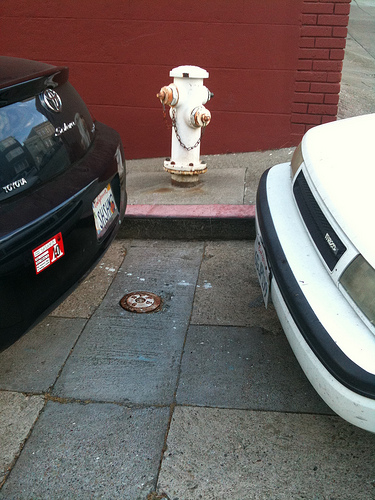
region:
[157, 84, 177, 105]
the hydrant is rusty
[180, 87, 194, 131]
the hydrant is white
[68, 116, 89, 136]
the car is black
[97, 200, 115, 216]
the tag is white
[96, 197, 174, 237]
the car is by the curb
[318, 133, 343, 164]
the car is white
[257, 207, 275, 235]
the bumper is black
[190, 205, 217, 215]
the curb is faded red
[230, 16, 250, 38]
the building is red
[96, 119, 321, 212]
the cars are by the hydrant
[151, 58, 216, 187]
the white fire hydrant on the sidewalk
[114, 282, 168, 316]
the hole cover on the road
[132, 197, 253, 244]
the red curb on the roadside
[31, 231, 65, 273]
the red sticker n the bumper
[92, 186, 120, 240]
the white liscense plate on the car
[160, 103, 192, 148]
the chain on the fire hydrant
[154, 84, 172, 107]
the cap of the fire hydrant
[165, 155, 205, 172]
the screws in the base of the hydrant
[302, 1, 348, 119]
the red brick wall on the building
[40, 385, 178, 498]
the wees growing in the cracks of the road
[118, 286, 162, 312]
a marker in the street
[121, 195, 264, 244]
a red painted curb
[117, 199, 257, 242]
indicates no parking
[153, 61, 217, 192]
a white fire hydrant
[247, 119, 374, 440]
a white car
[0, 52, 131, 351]
a black car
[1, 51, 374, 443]
cars are parked illegally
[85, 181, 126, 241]
California license plate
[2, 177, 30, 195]
a Toyota trade mark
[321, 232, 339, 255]
a Mazda trade mark on the grill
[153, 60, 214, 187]
Hydrant on the sidewalk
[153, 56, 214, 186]
Hydrant is on the sidewalk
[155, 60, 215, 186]
Fire hydrant on the sidewalk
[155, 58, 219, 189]
Fire hydrant is on the sidewalk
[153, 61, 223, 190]
White hydrant on the sidewalk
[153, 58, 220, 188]
White hydrant is on the sidewalk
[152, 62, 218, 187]
White fire hydrant on the sidewalk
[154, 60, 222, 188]
White fire hydrant is on the sidewalk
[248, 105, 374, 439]
White car parked on the street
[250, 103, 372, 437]
White car is parked on the street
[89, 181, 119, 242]
the license plate of a car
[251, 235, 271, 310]
the license plate of a car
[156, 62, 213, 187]
a white fire hydrant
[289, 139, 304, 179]
the headlight of a car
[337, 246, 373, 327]
the headlight of a car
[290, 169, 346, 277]
the front grill of a car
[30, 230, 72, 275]
a red sticker on a black car's bumper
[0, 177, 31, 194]
the word toyota on a black car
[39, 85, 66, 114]
a toyota logo on a car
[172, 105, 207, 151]
a chain on a fire hydrant